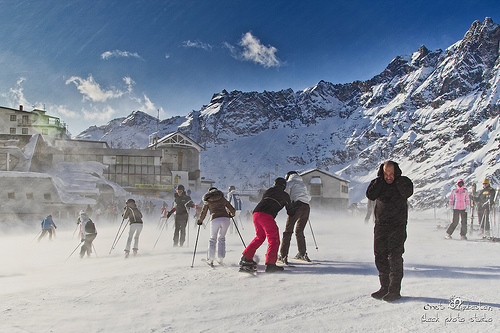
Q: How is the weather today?
A: It is cloudy.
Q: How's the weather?
A: It is cloudy.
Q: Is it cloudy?
A: Yes, it is cloudy.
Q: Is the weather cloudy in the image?
A: Yes, it is cloudy.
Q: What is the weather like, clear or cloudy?
A: It is cloudy.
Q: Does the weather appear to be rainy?
A: No, it is cloudy.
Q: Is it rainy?
A: No, it is cloudy.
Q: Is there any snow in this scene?
A: Yes, there is snow.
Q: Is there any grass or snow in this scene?
A: Yes, there is snow.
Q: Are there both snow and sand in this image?
A: No, there is snow but no sand.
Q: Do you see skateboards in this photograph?
A: No, there are no skateboards.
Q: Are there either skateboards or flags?
A: No, there are no skateboards or flags.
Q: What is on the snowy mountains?
A: The snow is on the mountains.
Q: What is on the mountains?
A: The snow is on the mountains.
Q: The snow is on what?
A: The snow is on the mountains.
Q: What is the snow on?
A: The snow is on the mountains.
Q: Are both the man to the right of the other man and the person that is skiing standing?
A: Yes, both the man and the person are standing.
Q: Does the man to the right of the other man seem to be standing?
A: Yes, the man is standing.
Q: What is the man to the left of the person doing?
A: The man is standing.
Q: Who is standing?
A: The man is standing.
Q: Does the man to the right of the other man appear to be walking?
A: No, the man is standing.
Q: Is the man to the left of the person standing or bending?
A: The man is standing.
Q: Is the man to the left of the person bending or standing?
A: The man is standing.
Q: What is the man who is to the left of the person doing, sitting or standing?
A: The man is standing.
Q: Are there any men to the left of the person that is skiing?
A: Yes, there is a man to the left of the person.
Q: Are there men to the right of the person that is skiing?
A: No, the man is to the left of the person.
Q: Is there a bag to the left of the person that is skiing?
A: No, there is a man to the left of the person.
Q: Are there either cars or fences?
A: No, there are no cars or fences.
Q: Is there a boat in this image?
A: No, there are no boats.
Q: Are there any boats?
A: No, there are no boats.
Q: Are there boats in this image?
A: No, there are no boats.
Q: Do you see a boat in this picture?
A: No, there are no boats.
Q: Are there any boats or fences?
A: No, there are no boats or fences.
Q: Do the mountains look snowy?
A: Yes, the mountains are snowy.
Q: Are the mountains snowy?
A: Yes, the mountains are snowy.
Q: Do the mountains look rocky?
A: No, the mountains are snowy.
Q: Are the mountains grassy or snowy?
A: The mountains are snowy.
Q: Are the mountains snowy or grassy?
A: The mountains are snowy.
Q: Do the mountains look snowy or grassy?
A: The mountains are snowy.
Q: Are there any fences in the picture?
A: No, there are no fences.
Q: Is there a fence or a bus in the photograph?
A: No, there are no fences or buses.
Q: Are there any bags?
A: No, there are no bags.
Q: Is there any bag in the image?
A: No, there are no bags.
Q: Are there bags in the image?
A: No, there are no bags.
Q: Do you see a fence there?
A: No, there are no fences.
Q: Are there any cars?
A: No, there are no cars.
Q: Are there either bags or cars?
A: No, there are no cars or bags.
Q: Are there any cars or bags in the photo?
A: No, there are no cars or bags.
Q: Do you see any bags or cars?
A: No, there are no cars or bags.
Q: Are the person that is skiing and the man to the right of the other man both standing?
A: Yes, both the person and the man are standing.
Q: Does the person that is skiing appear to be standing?
A: Yes, the person is standing.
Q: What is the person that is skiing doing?
A: The person is standing.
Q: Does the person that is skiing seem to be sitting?
A: No, the person is standing.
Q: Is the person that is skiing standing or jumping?
A: The person is standing.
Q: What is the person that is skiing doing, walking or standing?
A: The person is standing.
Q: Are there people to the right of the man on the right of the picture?
A: Yes, there is a person to the right of the man.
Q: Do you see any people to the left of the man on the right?
A: No, the person is to the right of the man.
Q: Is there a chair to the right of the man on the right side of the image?
A: No, there is a person to the right of the man.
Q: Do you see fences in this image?
A: No, there are no fences.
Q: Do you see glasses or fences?
A: No, there are no fences or glasses.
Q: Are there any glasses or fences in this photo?
A: No, there are no fences or glasses.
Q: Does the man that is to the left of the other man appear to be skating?
A: Yes, the man is skating.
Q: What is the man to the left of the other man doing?
A: The man is skating.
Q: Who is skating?
A: The man is skating.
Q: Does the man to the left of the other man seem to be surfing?
A: No, the man is skating.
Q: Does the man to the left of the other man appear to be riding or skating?
A: The man is skating.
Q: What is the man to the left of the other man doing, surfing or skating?
A: The man is skating.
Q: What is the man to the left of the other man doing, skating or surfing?
A: The man is skating.